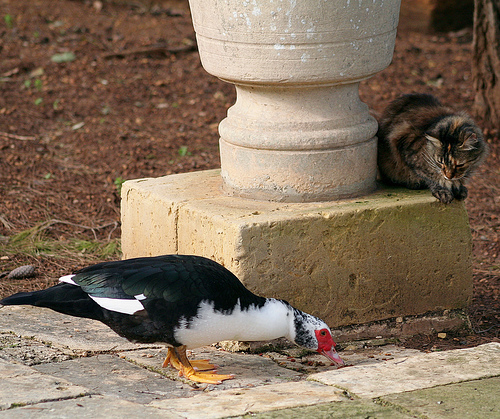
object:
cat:
[374, 92, 486, 204]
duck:
[0, 255, 344, 388]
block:
[115, 168, 477, 344]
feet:
[181, 364, 242, 386]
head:
[293, 313, 349, 367]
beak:
[325, 347, 347, 371]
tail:
[2, 285, 75, 314]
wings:
[65, 264, 177, 299]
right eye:
[319, 328, 331, 338]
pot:
[186, 0, 400, 198]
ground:
[1, 2, 496, 413]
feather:
[164, 281, 192, 302]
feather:
[238, 315, 262, 328]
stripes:
[378, 94, 430, 141]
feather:
[83, 285, 123, 298]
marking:
[312, 327, 332, 348]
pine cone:
[8, 263, 38, 280]